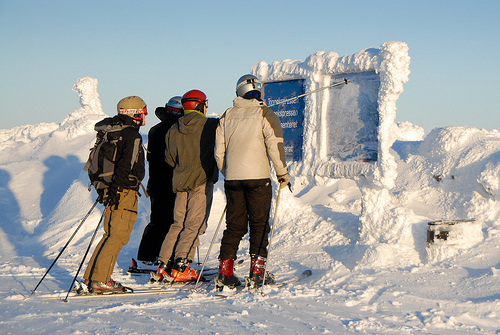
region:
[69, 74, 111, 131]
a sculpture made from snow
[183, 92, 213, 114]
a red helmet on head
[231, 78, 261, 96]
a silver helmet on head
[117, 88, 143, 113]
a green helmet on a head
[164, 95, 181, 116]
a blue helmet on a head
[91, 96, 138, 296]
a man wearing khaki pants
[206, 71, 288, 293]
a man wearing black pants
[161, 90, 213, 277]
a man wearing gray pants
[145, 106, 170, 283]
a man wearing a black jacket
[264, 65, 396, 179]
a sign covered in snow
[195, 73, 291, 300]
person standing in the snow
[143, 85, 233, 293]
person standing in the snow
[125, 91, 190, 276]
person standing in the snow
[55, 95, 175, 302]
person standing in the snow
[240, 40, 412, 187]
sign covered in snow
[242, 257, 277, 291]
boot used for skiing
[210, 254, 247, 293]
boot used for skiing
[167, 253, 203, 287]
boot used for skiing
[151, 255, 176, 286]
boot used for skiing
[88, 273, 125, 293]
boot used for skiing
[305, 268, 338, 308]
part of a snow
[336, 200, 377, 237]
part of a shade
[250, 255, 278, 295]
part of a hooker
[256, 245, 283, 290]
part of a hooker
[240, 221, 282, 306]
part of a hooker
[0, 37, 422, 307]
group of people standing in snow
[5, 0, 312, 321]
people wearing skis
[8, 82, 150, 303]
person holding ski poles behind them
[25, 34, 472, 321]
group of people looking at board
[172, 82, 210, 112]
person wearing red helmet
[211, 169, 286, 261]
person wearing black pants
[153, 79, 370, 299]
person using ski pole to point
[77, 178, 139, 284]
person wearing green pants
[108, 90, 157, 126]
person wearing green helmet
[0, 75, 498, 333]
four people standing in the snow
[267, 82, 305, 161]
blue and white sign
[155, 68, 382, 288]
person pointing at sign with ski pole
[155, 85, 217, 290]
person wearing a red helmet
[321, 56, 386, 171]
snow-covered sign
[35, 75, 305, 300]
four people wearing skis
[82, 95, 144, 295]
person wearing tan helmet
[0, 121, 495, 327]
snow-covered slope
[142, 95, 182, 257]
person wearing black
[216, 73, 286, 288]
person wearing silver helmet